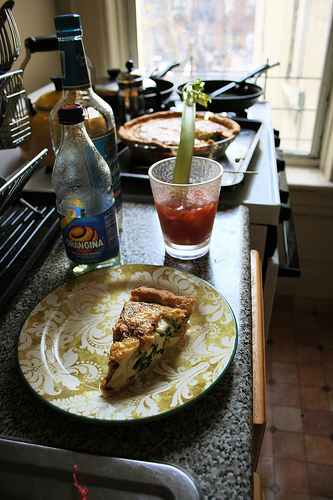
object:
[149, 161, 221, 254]
glass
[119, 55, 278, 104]
nonstick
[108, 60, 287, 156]
pans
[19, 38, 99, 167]
old fashioned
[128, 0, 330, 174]
large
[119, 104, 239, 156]
pie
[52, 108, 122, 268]
empty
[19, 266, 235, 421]
green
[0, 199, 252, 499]
counter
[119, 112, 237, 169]
tray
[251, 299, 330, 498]
brown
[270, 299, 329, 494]
different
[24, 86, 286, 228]
stove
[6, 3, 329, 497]
kitchen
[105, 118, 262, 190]
cookie sheet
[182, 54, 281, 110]
black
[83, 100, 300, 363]
oven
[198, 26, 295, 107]
bad subject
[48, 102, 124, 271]
bottles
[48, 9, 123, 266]
bottles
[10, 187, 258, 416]
countertop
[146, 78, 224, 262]
bloody mary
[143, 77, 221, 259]
cocktail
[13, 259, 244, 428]
plate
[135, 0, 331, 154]
window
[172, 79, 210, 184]
celery stalk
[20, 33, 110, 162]
kettle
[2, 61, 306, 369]
stove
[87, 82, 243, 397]
food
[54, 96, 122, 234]
alcohol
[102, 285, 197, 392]
pie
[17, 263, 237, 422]
design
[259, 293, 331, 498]
flooring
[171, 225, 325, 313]
bad sentance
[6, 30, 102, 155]
teapot